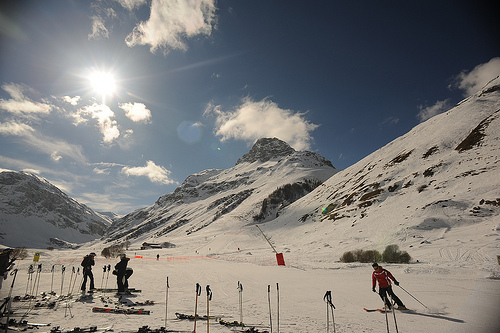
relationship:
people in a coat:
[371, 263, 409, 310] [369, 267, 396, 283]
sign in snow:
[32, 249, 44, 265] [11, 99, 495, 328]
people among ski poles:
[73, 246, 151, 310] [5, 267, 285, 326]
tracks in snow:
[149, 254, 278, 321] [15, 254, 495, 324]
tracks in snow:
[149, 254, 278, 321] [397, 129, 498, 271]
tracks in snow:
[149, 254, 278, 321] [230, 152, 330, 186]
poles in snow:
[170, 273, 241, 315] [179, 220, 410, 311]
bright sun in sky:
[81, 57, 134, 116] [247, 39, 321, 83]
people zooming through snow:
[371, 263, 409, 310] [282, 243, 319, 274]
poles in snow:
[154, 272, 406, 328] [178, 265, 265, 279]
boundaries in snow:
[95, 248, 258, 261] [18, 237, 408, 318]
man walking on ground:
[81, 252, 97, 290] [0, 248, 500, 333]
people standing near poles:
[111, 254, 133, 292] [377, 289, 409, 331]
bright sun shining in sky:
[88, 69, 121, 96] [111, 12, 420, 171]